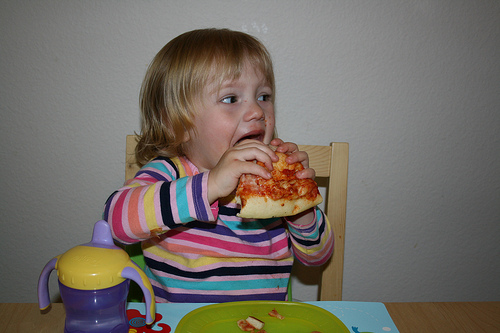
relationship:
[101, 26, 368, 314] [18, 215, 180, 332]
child has cup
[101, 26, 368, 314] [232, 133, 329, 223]
child has pizza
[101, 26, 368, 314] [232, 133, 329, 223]
child eats pizza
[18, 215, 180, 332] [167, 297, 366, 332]
cup near plate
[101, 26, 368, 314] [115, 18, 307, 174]
child has hair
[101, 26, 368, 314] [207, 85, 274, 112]
child has eyes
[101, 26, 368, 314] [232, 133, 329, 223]
child holds pizza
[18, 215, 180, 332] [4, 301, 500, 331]
cup on table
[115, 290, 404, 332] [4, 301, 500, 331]
place mat on table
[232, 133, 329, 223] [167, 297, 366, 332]
pizza on plate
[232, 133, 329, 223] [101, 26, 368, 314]
pizza on child